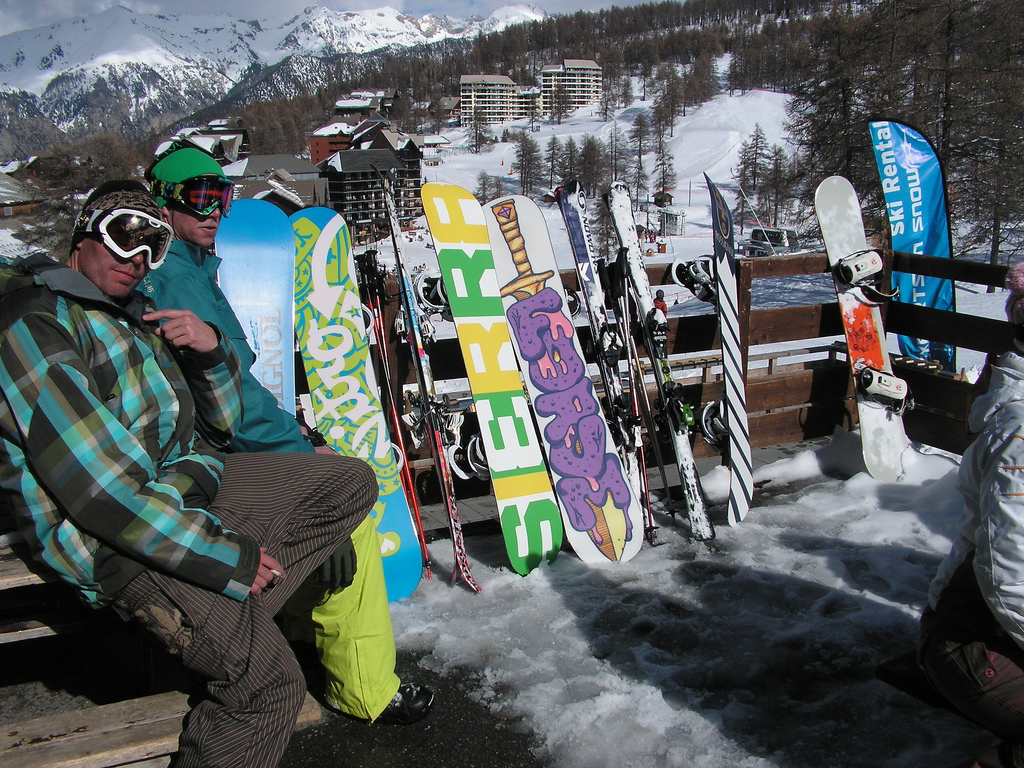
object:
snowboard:
[288, 206, 423, 604]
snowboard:
[421, 181, 564, 577]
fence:
[0, 247, 1024, 630]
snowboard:
[482, 194, 644, 570]